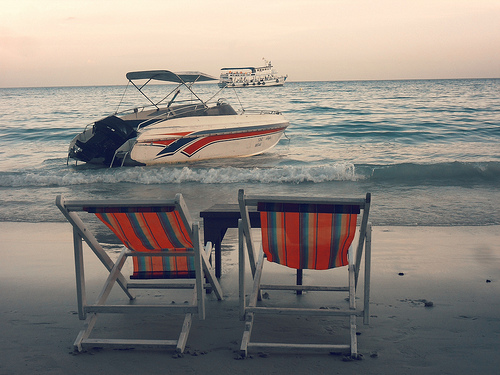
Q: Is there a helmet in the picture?
A: No, there are no helmets.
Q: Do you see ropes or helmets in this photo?
A: No, there are no helmets or ropes.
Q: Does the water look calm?
A: Yes, the water is calm.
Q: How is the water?
A: The water is calm.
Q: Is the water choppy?
A: No, the water is calm.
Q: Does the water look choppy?
A: No, the water is calm.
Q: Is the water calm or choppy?
A: The water is calm.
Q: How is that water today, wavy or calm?
A: The water is calm.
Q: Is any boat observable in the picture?
A: Yes, there is a boat.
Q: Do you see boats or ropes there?
A: Yes, there is a boat.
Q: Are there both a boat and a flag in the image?
A: No, there is a boat but no flags.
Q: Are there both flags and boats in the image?
A: No, there is a boat but no flags.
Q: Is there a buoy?
A: No, there are no buoys.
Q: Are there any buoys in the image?
A: No, there are no buoys.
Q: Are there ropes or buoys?
A: No, there are no buoys or ropes.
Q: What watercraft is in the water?
A: The watercraft is a boat.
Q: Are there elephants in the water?
A: No, there is a boat in the water.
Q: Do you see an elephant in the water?
A: No, there is a boat in the water.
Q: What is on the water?
A: The boat is on the water.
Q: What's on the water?
A: The boat is on the water.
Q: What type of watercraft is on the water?
A: The watercraft is a boat.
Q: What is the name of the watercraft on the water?
A: The watercraft is a boat.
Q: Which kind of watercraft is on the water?
A: The watercraft is a boat.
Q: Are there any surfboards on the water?
A: No, there is a boat on the water.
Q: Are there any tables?
A: Yes, there is a table.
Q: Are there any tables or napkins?
A: Yes, there is a table.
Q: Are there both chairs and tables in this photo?
A: Yes, there are both a table and a chair.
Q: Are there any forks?
A: No, there are no forks.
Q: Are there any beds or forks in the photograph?
A: No, there are no forks or beds.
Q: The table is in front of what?
A: The table is in front of the chair.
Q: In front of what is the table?
A: The table is in front of the chair.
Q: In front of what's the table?
A: The table is in front of the chair.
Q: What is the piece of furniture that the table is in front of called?
A: The piece of furniture is a chair.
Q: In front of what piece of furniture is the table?
A: The table is in front of the chair.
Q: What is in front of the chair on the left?
A: The table is in front of the chair.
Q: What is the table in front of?
A: The table is in front of the chair.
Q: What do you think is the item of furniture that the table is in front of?
A: The piece of furniture is a chair.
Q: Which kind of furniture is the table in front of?
A: The table is in front of the chair.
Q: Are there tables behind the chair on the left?
A: No, the table is in front of the chair.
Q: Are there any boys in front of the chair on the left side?
A: No, there is a table in front of the chair.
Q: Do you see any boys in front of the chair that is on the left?
A: No, there is a table in front of the chair.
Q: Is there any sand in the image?
A: Yes, there is sand.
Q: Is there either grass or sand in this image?
A: Yes, there is sand.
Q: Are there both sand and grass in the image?
A: No, there is sand but no grass.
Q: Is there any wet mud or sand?
A: Yes, there is wet sand.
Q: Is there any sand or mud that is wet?
A: Yes, the sand is wet.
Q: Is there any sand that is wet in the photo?
A: Yes, there is wet sand.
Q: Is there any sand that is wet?
A: Yes, there is sand that is wet.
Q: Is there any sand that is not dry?
A: Yes, there is wet sand.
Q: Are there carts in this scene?
A: No, there are no carts.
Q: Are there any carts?
A: No, there are no carts.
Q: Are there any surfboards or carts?
A: No, there are no carts or surfboards.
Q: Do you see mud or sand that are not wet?
A: No, there is sand but it is wet.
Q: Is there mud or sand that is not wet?
A: No, there is sand but it is wet.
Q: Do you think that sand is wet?
A: Yes, the sand is wet.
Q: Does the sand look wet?
A: Yes, the sand is wet.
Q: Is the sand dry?
A: No, the sand is wet.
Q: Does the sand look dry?
A: No, the sand is wet.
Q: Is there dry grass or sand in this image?
A: No, there is sand but it is wet.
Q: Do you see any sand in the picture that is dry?
A: No, there is sand but it is wet.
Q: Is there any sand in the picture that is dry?
A: No, there is sand but it is wet.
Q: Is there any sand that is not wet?
A: No, there is sand but it is wet.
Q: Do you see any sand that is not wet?
A: No, there is sand but it is wet.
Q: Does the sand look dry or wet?
A: The sand is wet.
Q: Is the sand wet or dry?
A: The sand is wet.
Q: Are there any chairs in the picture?
A: Yes, there is a chair.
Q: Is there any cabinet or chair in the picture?
A: Yes, there is a chair.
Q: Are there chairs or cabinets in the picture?
A: Yes, there is a chair.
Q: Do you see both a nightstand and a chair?
A: No, there is a chair but no nightstands.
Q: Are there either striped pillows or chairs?
A: Yes, there is a striped chair.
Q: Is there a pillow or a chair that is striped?
A: Yes, the chair is striped.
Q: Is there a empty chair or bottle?
A: Yes, there is an empty chair.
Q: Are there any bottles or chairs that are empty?
A: Yes, the chair is empty.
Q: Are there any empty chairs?
A: Yes, there is an empty chair.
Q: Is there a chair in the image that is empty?
A: Yes, there is a chair that is empty.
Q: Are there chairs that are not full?
A: Yes, there is a empty chair.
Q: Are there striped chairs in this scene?
A: Yes, there is a striped chair.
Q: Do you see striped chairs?
A: Yes, there is a striped chair.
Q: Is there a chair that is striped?
A: Yes, there is a chair that is striped.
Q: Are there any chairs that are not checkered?
A: Yes, there is a striped chair.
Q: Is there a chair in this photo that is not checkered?
A: Yes, there is a striped chair.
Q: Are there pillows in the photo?
A: No, there are no pillows.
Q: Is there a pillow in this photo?
A: No, there are no pillows.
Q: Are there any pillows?
A: No, there are no pillows.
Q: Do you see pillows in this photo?
A: No, there are no pillows.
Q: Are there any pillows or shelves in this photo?
A: No, there are no pillows or shelves.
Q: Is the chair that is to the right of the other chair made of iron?
A: Yes, the chair is made of iron.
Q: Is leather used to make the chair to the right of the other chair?
A: No, the chair is made of iron.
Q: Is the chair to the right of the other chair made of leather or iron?
A: The chair is made of iron.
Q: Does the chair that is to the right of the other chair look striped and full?
A: No, the chair is striped but empty.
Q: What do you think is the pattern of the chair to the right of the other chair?
A: The chair is striped.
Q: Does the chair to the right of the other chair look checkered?
A: No, the chair is striped.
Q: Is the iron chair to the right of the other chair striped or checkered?
A: The chair is striped.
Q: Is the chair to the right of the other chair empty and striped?
A: Yes, the chair is empty and striped.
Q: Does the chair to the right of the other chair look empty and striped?
A: Yes, the chair is empty and striped.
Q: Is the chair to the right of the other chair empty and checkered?
A: No, the chair is empty but striped.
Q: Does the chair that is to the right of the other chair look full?
A: No, the chair is empty.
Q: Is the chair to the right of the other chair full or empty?
A: The chair is empty.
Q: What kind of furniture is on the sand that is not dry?
A: The piece of furniture is a chair.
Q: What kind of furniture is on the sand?
A: The piece of furniture is a chair.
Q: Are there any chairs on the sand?
A: Yes, there is a chair on the sand.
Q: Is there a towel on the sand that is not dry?
A: No, there is a chair on the sand.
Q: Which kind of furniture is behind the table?
A: The piece of furniture is a chair.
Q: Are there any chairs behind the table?
A: Yes, there is a chair behind the table.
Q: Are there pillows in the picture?
A: No, there are no pillows.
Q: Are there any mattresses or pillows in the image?
A: No, there are no pillows or mattresses.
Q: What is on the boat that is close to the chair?
A: The canopy is on the boat.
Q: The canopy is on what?
A: The canopy is on the boat.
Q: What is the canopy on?
A: The canopy is on the boat.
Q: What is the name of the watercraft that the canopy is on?
A: The watercraft is a boat.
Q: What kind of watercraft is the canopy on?
A: The canopy is on the boat.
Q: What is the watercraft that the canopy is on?
A: The watercraft is a boat.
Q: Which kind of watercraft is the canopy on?
A: The canopy is on the boat.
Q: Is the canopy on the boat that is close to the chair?
A: Yes, the canopy is on the boat.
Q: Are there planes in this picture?
A: No, there are no planes.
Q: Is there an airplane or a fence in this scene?
A: No, there are no airplanes or fences.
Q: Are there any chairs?
A: Yes, there is a chair.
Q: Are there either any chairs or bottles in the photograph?
A: Yes, there is a chair.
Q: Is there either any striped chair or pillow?
A: Yes, there is a striped chair.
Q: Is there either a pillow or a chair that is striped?
A: Yes, the chair is striped.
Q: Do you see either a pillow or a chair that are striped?
A: Yes, the chair is striped.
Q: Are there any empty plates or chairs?
A: Yes, there is an empty chair.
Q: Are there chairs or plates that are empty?
A: Yes, the chair is empty.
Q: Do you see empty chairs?
A: Yes, there is an empty chair.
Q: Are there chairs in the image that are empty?
A: Yes, there is a chair that is empty.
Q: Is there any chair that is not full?
A: Yes, there is a empty chair.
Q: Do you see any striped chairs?
A: Yes, there is a striped chair.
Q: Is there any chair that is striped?
A: Yes, there is a chair that is striped.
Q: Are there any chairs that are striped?
A: Yes, there is a chair that is striped.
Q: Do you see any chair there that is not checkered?
A: Yes, there is a striped chair.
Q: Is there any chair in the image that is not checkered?
A: Yes, there is a striped chair.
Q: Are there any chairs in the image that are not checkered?
A: Yes, there is a striped chair.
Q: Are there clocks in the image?
A: No, there are no clocks.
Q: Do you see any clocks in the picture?
A: No, there are no clocks.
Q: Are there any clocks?
A: No, there are no clocks.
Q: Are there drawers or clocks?
A: No, there are no clocks or drawers.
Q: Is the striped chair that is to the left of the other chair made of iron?
A: Yes, the chair is made of iron.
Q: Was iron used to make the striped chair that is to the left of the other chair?
A: Yes, the chair is made of iron.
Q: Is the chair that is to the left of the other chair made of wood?
A: No, the chair is made of iron.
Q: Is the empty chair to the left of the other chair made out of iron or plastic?
A: The chair is made of iron.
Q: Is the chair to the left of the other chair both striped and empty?
A: Yes, the chair is striped and empty.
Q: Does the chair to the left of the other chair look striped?
A: Yes, the chair is striped.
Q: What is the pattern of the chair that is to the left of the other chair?
A: The chair is striped.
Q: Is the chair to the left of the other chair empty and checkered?
A: No, the chair is empty but striped.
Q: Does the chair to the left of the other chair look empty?
A: Yes, the chair is empty.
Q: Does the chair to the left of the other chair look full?
A: No, the chair is empty.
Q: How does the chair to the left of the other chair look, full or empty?
A: The chair is empty.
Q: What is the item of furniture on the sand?
A: The piece of furniture is a chair.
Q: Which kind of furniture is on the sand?
A: The piece of furniture is a chair.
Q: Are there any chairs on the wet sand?
A: Yes, there is a chair on the sand.